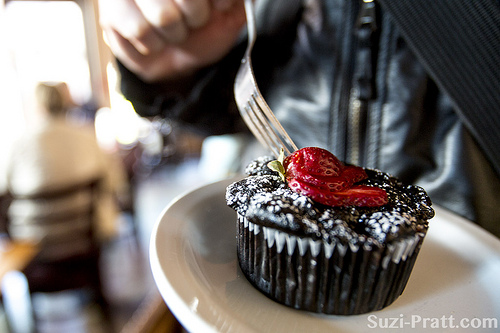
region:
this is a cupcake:
[222, 143, 437, 320]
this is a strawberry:
[275, 141, 385, 201]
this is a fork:
[231, 1, 291, 157]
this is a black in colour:
[281, 31, 356, 123]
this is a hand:
[96, 0, 236, 71]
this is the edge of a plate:
[146, 160, 201, 330]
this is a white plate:
[145, 135, 495, 326]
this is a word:
[360, 310, 495, 330]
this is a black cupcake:
[225, 145, 431, 310]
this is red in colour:
[285, 142, 386, 202]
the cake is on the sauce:
[227, 154, 429, 320]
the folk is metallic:
[233, 68, 302, 155]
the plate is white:
[161, 220, 244, 330]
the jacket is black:
[298, 60, 495, 202]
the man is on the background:
[6, 85, 123, 253]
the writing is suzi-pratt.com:
[370, 312, 495, 332]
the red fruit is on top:
[293, 151, 385, 204]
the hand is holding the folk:
[120, 61, 302, 154]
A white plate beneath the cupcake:
[150, 173, 499, 329]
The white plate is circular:
[153, 176, 496, 332]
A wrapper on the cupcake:
[236, 211, 426, 316]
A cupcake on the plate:
[226, 149, 437, 313]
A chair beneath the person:
[0, 174, 111, 329]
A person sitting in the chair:
[4, 84, 123, 260]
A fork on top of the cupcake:
[233, 2, 298, 159]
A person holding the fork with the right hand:
[98, 0, 241, 80]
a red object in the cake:
[263, 136, 389, 224]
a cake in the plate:
[213, 131, 486, 328]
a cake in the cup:
[206, 161, 443, 323]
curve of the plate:
[146, 213, 224, 323]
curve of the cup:
[115, 182, 242, 331]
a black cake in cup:
[211, 165, 426, 292]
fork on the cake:
[207, 75, 318, 151]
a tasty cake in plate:
[225, 145, 420, 316]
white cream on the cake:
[255, 205, 312, 260]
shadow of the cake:
[419, 246, 470, 294]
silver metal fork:
[232, 0, 304, 163]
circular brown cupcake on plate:
[223, 144, 437, 316]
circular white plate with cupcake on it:
[143, 165, 498, 331]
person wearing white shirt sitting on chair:
[2, 73, 122, 328]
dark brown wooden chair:
[1, 165, 112, 331]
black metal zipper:
[354, 0, 381, 40]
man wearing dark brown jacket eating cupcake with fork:
[94, 0, 498, 267]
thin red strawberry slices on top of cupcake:
[280, 144, 392, 211]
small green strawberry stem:
[260, 145, 288, 182]